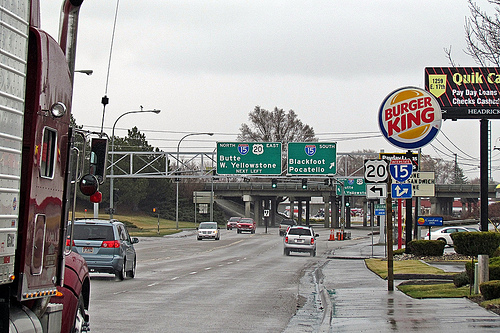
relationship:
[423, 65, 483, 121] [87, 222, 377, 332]
billboard standing next to road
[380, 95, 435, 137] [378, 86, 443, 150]
burger king printed on sign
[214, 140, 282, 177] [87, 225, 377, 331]
street sign hanging above road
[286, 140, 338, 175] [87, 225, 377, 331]
sign hanging above road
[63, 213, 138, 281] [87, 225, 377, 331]
car driving on road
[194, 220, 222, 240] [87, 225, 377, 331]
car driving on road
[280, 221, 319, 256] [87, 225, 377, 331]
car driving on road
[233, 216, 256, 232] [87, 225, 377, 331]
car driving on road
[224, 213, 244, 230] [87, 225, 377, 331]
car driving on road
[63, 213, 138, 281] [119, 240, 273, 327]
car on road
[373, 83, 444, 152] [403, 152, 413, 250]
sign on pole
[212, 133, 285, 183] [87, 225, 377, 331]
sign over road